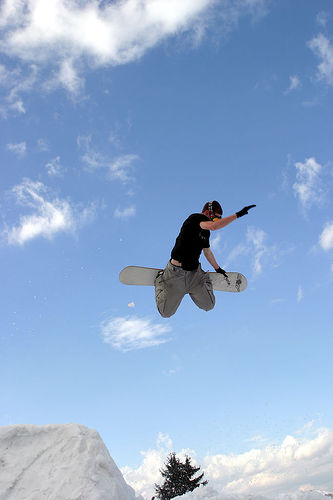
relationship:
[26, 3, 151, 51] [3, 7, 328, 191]
clouds in sky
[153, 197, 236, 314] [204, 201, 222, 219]
man wearing goggles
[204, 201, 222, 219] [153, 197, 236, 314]
goggles are on man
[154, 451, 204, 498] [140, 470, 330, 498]
tree in snow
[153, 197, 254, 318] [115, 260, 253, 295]
man riding snowboard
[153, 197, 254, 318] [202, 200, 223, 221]
man wearing goggles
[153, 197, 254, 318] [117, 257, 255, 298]
man using snowboard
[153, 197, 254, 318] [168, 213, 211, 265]
man wearing shirt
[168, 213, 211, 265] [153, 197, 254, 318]
shirt on man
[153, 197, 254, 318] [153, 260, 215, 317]
man wearing pants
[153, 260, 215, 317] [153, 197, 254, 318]
pants are on man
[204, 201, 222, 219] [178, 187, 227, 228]
goggles on head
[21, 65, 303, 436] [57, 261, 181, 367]
sky with clouds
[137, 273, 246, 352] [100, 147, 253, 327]
pants on snowboarder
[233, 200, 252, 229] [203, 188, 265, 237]
gloves on hands